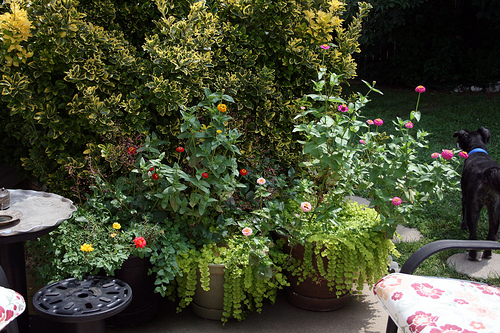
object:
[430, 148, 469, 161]
flowers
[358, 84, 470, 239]
bush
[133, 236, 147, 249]
flower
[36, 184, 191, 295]
bush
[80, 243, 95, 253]
flower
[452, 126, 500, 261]
dog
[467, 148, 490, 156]
collar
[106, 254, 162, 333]
pot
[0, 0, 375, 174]
leaves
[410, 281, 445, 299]
flower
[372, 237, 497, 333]
chair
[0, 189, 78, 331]
table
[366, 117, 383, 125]
flowers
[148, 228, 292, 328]
leaves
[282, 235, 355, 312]
pot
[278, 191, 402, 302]
plant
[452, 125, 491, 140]
ears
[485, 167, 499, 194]
tail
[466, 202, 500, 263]
legs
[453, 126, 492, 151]
head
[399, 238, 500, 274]
arm rest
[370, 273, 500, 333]
cushion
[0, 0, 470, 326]
plants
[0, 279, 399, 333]
ground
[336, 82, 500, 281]
grass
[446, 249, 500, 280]
stepping stone